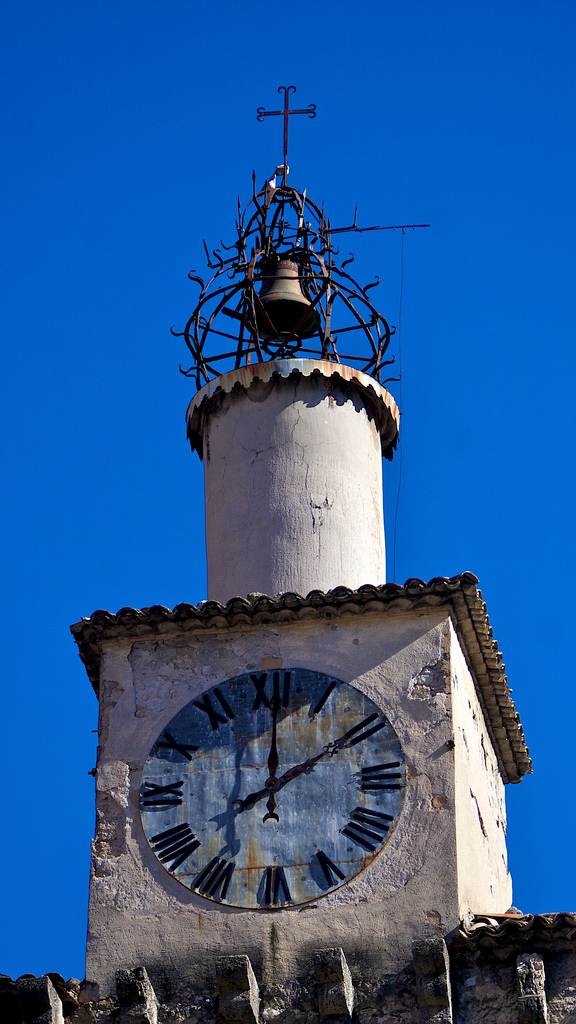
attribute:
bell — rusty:
[231, 237, 326, 343]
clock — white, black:
[104, 662, 446, 914]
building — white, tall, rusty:
[79, 89, 517, 1009]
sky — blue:
[7, 4, 574, 718]